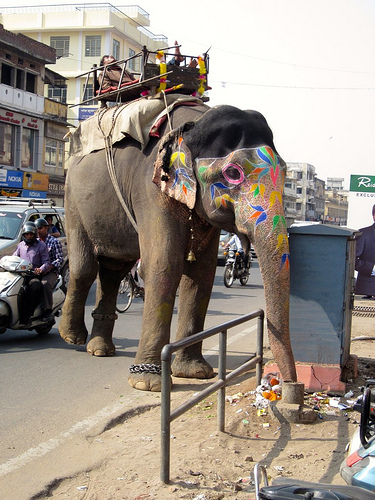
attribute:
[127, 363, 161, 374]
chains — silver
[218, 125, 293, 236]
face — elephant's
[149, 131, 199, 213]
ear — elephant's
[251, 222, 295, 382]
trunk — grey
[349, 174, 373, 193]
sign — green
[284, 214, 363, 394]
post — big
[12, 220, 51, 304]
man — sitting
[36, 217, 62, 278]
man — sitting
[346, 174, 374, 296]
sign — white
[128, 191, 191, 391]
leg —  front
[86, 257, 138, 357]
leg — back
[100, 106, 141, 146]
sheet — white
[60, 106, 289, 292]
elephant — standing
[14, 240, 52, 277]
shirt — purple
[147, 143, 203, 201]
ear — painted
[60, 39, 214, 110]
contraption — carrying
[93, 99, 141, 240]
rope — brown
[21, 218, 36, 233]
helmet — black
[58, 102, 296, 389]
elephant — chained-up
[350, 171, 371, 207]
top — green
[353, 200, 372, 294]
man's picture — man's 